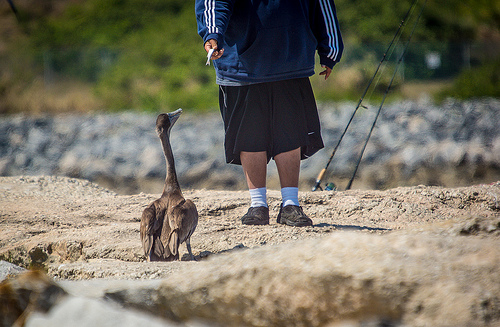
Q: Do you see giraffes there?
A: No, there are no giraffes.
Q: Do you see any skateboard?
A: No, there are no skateboards.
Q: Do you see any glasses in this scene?
A: No, there are no glasses.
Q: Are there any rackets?
A: No, there are no rackets.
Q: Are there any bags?
A: No, there are no bags.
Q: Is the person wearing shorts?
A: Yes, the person is wearing shorts.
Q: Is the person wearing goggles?
A: No, the person is wearing shorts.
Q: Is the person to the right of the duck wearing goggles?
A: No, the person is wearing shorts.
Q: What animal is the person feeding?
A: The person is feeding the duck.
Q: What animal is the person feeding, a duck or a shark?
A: The person is feeding a duck.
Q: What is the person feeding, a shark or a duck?
A: The person is feeding a duck.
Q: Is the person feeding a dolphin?
A: No, the person is feeding the duck.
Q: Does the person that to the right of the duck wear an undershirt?
A: Yes, the person wears an undershirt.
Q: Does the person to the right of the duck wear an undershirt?
A: Yes, the person wears an undershirt.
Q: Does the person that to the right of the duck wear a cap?
A: No, the person wears an undershirt.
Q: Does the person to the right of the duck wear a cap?
A: No, the person wears an undershirt.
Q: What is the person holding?
A: The person is holding the fish.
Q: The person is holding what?
A: The person is holding the fish.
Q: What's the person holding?
A: The person is holding the fish.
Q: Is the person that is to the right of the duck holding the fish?
A: Yes, the person is holding the fish.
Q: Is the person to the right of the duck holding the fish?
A: Yes, the person is holding the fish.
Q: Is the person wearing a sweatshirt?
A: Yes, the person is wearing a sweatshirt.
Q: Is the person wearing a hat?
A: No, the person is wearing a sweatshirt.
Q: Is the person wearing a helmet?
A: No, the person is wearing a shoe.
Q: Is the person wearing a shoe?
A: Yes, the person is wearing a shoe.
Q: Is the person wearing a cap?
A: No, the person is wearing a shoe.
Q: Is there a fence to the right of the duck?
A: No, there is a person to the right of the duck.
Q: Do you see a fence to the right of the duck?
A: No, there is a person to the right of the duck.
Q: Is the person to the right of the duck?
A: Yes, the person is to the right of the duck.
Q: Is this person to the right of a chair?
A: No, the person is to the right of the duck.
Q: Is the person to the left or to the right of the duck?
A: The person is to the right of the duck.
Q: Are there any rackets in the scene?
A: No, there are no rackets.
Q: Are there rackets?
A: No, there are no rackets.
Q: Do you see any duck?
A: Yes, there is a duck.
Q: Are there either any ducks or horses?
A: Yes, there is a duck.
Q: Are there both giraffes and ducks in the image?
A: No, there is a duck but no giraffes.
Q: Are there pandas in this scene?
A: No, there are no pandas.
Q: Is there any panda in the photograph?
A: No, there are no pandas.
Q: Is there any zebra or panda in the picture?
A: No, there are no pandas or zebras.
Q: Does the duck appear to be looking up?
A: Yes, the duck is looking up.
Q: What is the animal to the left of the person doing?
A: The duck is looking up.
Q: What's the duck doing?
A: The duck is looking up.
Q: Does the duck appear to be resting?
A: No, the duck is looking up.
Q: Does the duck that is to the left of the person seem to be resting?
A: No, the duck is looking up.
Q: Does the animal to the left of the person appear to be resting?
A: No, the duck is looking up.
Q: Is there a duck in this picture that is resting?
A: No, there is a duck but it is looking up.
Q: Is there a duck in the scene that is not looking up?
A: No, there is a duck but it is looking up.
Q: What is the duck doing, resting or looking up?
A: The duck is looking up.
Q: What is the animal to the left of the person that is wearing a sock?
A: The animal is a duck.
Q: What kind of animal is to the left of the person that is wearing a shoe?
A: The animal is a duck.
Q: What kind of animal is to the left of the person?
A: The animal is a duck.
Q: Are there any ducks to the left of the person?
A: Yes, there is a duck to the left of the person.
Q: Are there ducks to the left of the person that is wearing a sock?
A: Yes, there is a duck to the left of the person.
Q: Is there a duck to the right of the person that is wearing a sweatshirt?
A: No, the duck is to the left of the person.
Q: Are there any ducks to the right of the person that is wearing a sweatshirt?
A: No, the duck is to the left of the person.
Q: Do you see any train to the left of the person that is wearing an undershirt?
A: No, there is a duck to the left of the person.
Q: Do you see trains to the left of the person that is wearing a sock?
A: No, there is a duck to the left of the person.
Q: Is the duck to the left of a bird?
A: No, the duck is to the left of a person.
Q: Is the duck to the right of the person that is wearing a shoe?
A: No, the duck is to the left of the person.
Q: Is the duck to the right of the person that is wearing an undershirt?
A: No, the duck is to the left of the person.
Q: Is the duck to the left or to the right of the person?
A: The duck is to the left of the person.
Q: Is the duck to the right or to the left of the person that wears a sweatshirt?
A: The duck is to the left of the person.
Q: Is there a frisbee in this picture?
A: No, there are no frisbees.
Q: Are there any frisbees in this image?
A: No, there are no frisbees.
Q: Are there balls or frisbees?
A: No, there are no frisbees or balls.